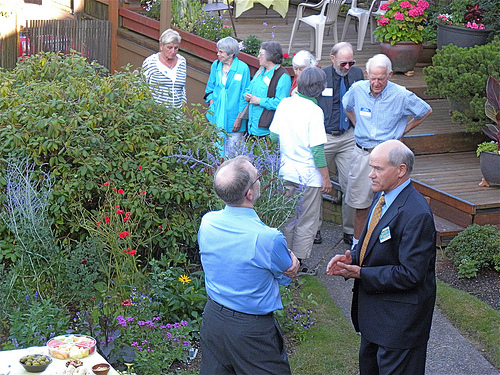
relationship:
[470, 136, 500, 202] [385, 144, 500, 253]
plants on decking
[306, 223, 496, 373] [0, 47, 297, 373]
pathway in garden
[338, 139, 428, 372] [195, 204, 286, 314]
man in shirt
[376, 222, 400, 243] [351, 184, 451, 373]
badge attached to suit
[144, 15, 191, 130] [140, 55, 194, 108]
woman in shirt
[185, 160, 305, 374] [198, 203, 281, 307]
man in shirt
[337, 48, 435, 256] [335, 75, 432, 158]
man in shirt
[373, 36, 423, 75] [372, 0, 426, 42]
planter with flowers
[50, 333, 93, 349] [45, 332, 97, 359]
fruit assortment in container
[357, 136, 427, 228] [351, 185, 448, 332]
man in suit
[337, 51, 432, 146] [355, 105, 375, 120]
man with name tag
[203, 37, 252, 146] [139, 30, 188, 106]
older woman wearing older woman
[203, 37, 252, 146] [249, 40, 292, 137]
older woman wearing older woman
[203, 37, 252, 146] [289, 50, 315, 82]
older woman wearing older woman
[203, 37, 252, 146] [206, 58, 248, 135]
older woman wearing turquoise jacket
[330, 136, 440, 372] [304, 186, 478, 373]
bald man wearing suit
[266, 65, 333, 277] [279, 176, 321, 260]
woman wearing pants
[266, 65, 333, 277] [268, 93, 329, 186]
woman wearing white shirt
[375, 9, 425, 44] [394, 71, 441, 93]
plant on a deck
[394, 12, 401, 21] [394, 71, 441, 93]
flower on a deck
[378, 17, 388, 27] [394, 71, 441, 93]
flower on a deck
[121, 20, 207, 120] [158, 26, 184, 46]
woman with gray hair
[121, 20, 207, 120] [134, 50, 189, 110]
woman with striped shirt